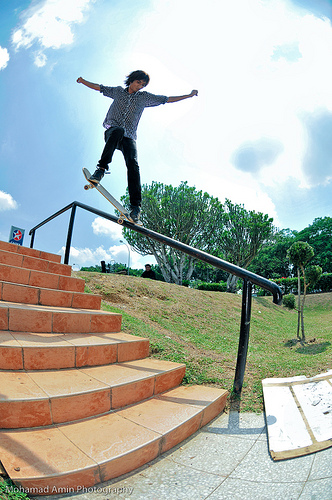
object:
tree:
[287, 240, 321, 339]